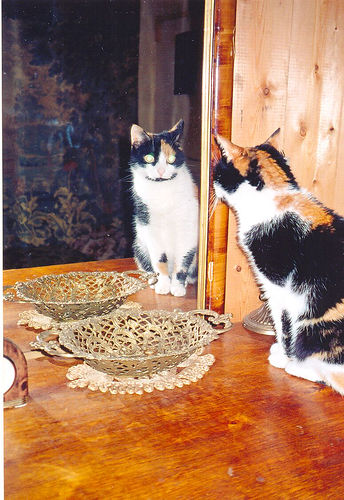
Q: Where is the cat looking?
A: In the mirror.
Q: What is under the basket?
A: A Crocheted doily.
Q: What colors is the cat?
A: Black, orange and white.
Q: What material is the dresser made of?
A: Wood.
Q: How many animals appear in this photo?
A: One.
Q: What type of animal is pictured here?
A: Cat.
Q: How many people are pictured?
A: Zero.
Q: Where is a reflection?
A: In the mirror.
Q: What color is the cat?
A: White, brown and black.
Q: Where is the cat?
A: On a dresser.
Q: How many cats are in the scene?
A: One.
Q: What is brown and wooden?
A: The dresser.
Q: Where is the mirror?
A: On the wall.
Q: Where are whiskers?
A: On cat's face.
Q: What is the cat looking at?
A: Reflection.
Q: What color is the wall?
A: Brown.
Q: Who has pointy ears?
A: The cat.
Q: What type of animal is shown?
A: Cat.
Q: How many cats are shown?
A: 1.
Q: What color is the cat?
A: Brown, black, and white.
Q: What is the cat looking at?
A: Reflection in the mirror.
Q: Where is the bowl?
A: Beside the cat.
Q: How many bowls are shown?
A: 1.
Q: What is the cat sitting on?
A: Dresser.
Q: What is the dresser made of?
A: Wood.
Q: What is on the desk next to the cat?
A: A bowl.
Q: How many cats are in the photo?
A: 2.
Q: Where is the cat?
A: On the desk.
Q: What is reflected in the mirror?
A: A cat.